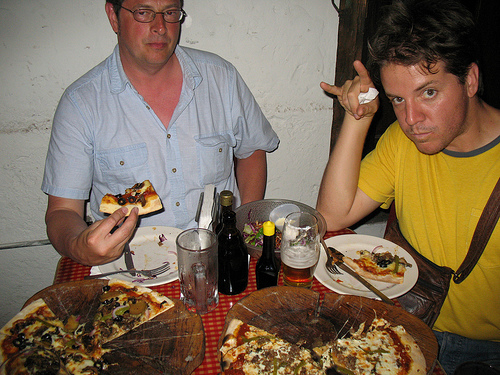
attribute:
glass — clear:
[173, 226, 222, 313]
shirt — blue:
[40, 53, 275, 241]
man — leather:
[306, 32, 499, 277]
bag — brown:
[342, 194, 477, 356]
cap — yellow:
[261, 221, 276, 236]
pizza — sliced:
[82, 272, 177, 352]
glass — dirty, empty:
[173, 224, 225, 317]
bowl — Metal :
[232, 195, 328, 264]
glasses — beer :
[175, 210, 323, 314]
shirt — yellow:
[349, 114, 499, 339]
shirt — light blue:
[38, 36, 283, 256]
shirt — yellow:
[353, 153, 486, 309]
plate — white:
[300, 207, 433, 318]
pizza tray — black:
[223, 283, 443, 373]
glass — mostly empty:
[278, 209, 323, 284]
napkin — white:
[357, 87, 381, 104]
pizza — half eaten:
[348, 250, 411, 280]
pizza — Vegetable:
[0, 297, 97, 373]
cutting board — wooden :
[105, 307, 194, 372]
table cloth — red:
[4, 242, 486, 372]